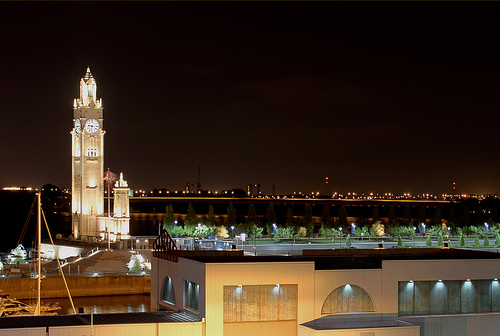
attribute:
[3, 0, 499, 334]
photograph — night time, a city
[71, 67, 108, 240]
clock tower — large, brick, very lit up, very bright, lit up, tan, illuminated, bright with lights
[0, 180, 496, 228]
city lights — distant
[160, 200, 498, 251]
trees — green, in a row, partially lit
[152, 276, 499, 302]
lights — shining down, blue white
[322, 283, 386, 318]
window — arched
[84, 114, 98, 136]
clock — white, telling time, numbered in black, front faced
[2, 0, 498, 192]
sky — black, clear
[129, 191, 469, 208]
lights — in a row, distant, yellow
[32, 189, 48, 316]
pole — white, boat mast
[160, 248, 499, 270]
roof — flat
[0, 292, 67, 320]
boat — parked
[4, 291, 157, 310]
water — canal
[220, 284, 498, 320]
windows — lit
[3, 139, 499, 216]
skyline — lit up with lights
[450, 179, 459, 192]
lights — red, small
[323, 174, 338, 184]
lights — red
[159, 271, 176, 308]
window — arched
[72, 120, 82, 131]
clock — side faced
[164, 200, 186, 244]
tree — illuminated by light